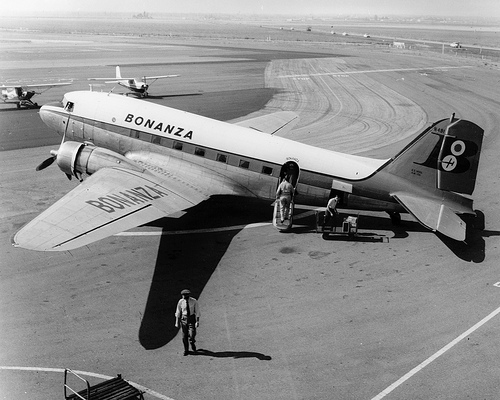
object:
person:
[162, 273, 214, 361]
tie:
[185, 299, 192, 322]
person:
[274, 166, 300, 220]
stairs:
[271, 199, 294, 230]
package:
[343, 214, 358, 234]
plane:
[7, 82, 490, 256]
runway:
[227, 47, 426, 154]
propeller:
[33, 128, 78, 187]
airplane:
[83, 55, 181, 102]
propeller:
[141, 84, 150, 96]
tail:
[388, 106, 487, 246]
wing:
[7, 154, 234, 254]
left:
[115, 149, 249, 202]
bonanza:
[80, 173, 172, 218]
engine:
[51, 139, 145, 177]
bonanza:
[124, 111, 194, 144]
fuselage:
[94, 86, 343, 195]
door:
[273, 157, 303, 194]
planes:
[0, 80, 73, 110]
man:
[316, 192, 342, 242]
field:
[0, 2, 499, 65]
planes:
[83, 62, 177, 93]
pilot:
[163, 287, 208, 326]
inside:
[285, 166, 296, 174]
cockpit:
[47, 86, 87, 118]